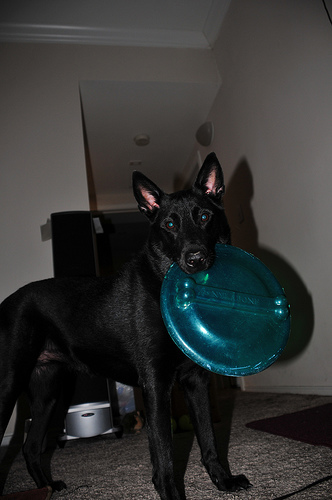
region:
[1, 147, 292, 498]
a dog holding a frisbee in its mouth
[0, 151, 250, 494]
a dog with black fur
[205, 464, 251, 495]
the paw of a dog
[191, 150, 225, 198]
the ear of a dog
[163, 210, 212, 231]
the eyes of a dog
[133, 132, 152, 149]
a smoke detector on the ceiling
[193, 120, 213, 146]
a light on the wall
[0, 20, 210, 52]
white molding near the ceiling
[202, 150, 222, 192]
pink skin a dog's ear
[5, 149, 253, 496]
a dog with shinny black fur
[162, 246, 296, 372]
SHINY BLUE FRISBEE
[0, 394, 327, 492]
GREY CARPET ON THE FLOOR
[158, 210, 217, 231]
BLUE EYES OF A DOG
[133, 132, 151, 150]
FIRE ALARM ON THE CEILING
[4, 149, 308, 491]
BLACK DOG HOLDING A FRISBEE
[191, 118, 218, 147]
WALL LIGHT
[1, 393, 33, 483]
TAIL OF THE BLACK DOG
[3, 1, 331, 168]
BEIGE WALLS AND WHITE CEILING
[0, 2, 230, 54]
WHITE MOULDING ON THE WALL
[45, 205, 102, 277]
BLACK SPEAKER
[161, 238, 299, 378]
Green frisbee in the dog mouth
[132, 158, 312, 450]
Green frisbee in the dog mouth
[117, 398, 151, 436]
toy doll on the floor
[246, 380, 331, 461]
rug on the floor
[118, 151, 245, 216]
dog ears perked up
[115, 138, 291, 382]
Green frisbee in the dog mouth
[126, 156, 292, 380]
Green frisbee in the dog mouth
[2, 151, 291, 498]
A dog with a frisbee.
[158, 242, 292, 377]
A frisbee in a dogs mouth.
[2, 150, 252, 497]
A black dog on carpet.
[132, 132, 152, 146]
A smoke detector on a ceiling.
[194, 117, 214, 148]
A light on a wall.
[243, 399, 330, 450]
Part of a rug.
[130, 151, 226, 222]
A dogs two ears.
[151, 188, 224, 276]
A dogs head and face.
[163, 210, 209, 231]
A dogs two eyes.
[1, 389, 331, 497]
Brown carpet on the floor.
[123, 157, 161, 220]
pink and black ear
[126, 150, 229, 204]
two pointy ears on the top of the head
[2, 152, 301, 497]
black dog holding a frisbee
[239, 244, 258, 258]
bite marks on top of the toy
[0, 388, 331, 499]
carpet on the ground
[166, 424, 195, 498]
shadow on the ground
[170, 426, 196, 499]
shadow from the dog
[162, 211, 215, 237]
two blue eyes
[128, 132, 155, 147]
smoke detector on the ceiling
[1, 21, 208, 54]
white trim on the top of the wall